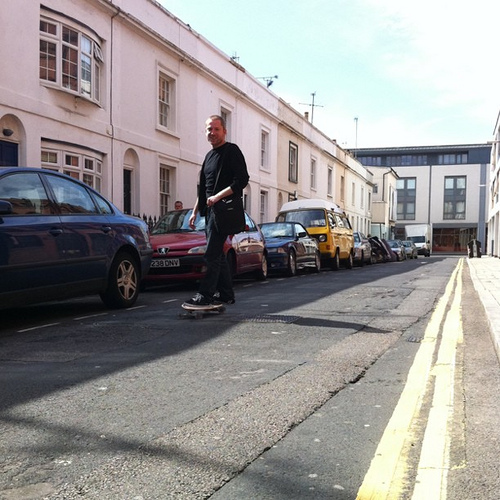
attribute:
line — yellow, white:
[386, 371, 451, 487]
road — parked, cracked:
[2, 152, 433, 419]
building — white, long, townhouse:
[366, 131, 500, 254]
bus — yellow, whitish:
[272, 195, 356, 279]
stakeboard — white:
[170, 295, 227, 322]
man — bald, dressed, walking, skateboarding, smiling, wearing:
[168, 112, 248, 314]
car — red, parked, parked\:
[151, 203, 274, 287]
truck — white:
[404, 225, 438, 256]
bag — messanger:
[213, 164, 247, 230]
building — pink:
[0, 0, 381, 245]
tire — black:
[102, 251, 141, 304]